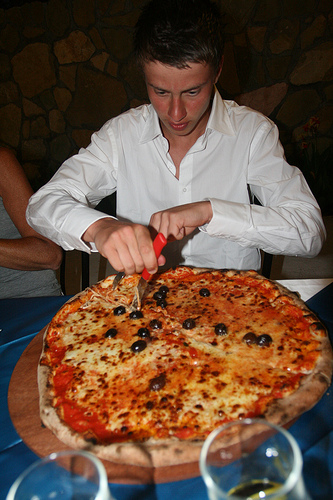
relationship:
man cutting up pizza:
[13, 11, 325, 297] [37, 261, 331, 469]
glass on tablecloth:
[197, 415, 305, 498] [1, 288, 329, 498]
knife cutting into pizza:
[129, 231, 167, 311] [37, 261, 331, 469]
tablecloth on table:
[1, 288, 329, 498] [3, 296, 332, 497]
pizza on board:
[37, 261, 331, 469] [7, 325, 296, 485]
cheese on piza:
[58, 280, 301, 433] [26, 250, 312, 480]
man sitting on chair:
[22, 11, 325, 297] [3, 195, 96, 293]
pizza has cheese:
[37, 261, 331, 469] [44, 279, 322, 437]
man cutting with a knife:
[13, 11, 325, 297] [126, 232, 168, 312]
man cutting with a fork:
[13, 11, 325, 297] [109, 227, 153, 296]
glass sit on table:
[197, 416, 309, 498] [3, 296, 332, 497]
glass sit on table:
[14, 442, 109, 497] [3, 296, 332, 497]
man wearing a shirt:
[13, 11, 325, 297] [24, 92, 324, 270]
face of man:
[149, 63, 204, 130] [26, 27, 332, 283]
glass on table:
[197, 416, 309, 498] [3, 296, 332, 497]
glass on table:
[6, 442, 109, 499] [3, 296, 332, 497]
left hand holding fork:
[149, 209, 214, 250] [105, 265, 128, 285]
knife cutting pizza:
[123, 227, 170, 306] [37, 261, 331, 469]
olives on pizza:
[238, 328, 276, 349] [37, 261, 331, 469]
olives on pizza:
[152, 284, 215, 310] [37, 261, 331, 469]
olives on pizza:
[177, 313, 234, 339] [37, 261, 331, 469]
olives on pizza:
[100, 301, 166, 349] [37, 261, 331, 469]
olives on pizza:
[145, 370, 170, 392] [37, 261, 331, 469]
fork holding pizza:
[107, 272, 129, 286] [37, 261, 331, 469]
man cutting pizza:
[13, 11, 325, 297] [37, 261, 331, 469]